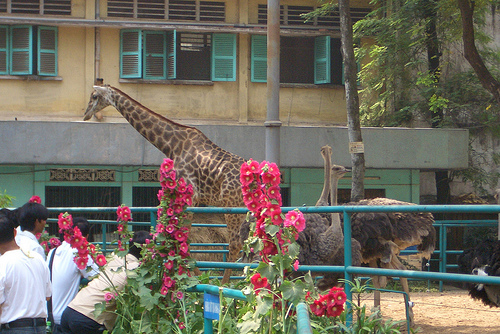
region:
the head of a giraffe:
[83, 75, 118, 120]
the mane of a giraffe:
[109, 84, 197, 129]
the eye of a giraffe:
[88, 90, 100, 101]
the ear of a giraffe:
[92, 82, 113, 97]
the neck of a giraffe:
[112, 86, 188, 158]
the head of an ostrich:
[327, 159, 358, 181]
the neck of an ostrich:
[325, 175, 343, 227]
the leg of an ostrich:
[390, 252, 421, 324]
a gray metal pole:
[252, 0, 290, 167]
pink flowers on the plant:
[236, 153, 287, 228]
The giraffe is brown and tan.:
[84, 76, 271, 205]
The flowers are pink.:
[229, 157, 317, 277]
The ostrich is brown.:
[313, 152, 443, 296]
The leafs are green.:
[353, 9, 480, 153]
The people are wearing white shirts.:
[5, 194, 149, 333]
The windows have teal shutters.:
[7, 8, 355, 93]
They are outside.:
[15, 26, 480, 331]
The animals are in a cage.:
[70, 79, 468, 314]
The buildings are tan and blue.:
[29, 23, 137, 236]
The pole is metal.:
[247, 26, 296, 183]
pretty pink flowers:
[236, 160, 314, 307]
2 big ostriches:
[303, 139, 455, 286]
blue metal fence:
[323, 205, 483, 329]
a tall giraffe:
[75, 80, 275, 260]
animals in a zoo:
[81, 80, 444, 285]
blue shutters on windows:
[118, 29, 252, 88]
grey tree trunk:
[335, 23, 371, 198]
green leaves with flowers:
[242, 220, 312, 322]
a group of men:
[3, 196, 149, 326]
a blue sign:
[199, 285, 236, 325]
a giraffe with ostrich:
[71, 60, 473, 321]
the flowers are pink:
[85, 162, 348, 321]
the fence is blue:
[306, 190, 420, 317]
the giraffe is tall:
[31, 48, 321, 271]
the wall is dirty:
[8, 12, 397, 197]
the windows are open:
[43, 23, 387, 109]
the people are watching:
[0, 197, 143, 331]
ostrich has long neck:
[265, 115, 365, 280]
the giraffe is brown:
[71, 79, 281, 279]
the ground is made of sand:
[355, 280, 427, 324]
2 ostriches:
[288, 142, 442, 310]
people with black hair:
[0, 197, 72, 257]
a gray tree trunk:
[329, 0, 388, 188]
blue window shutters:
[125, 24, 239, 86]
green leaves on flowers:
[239, 216, 302, 332]